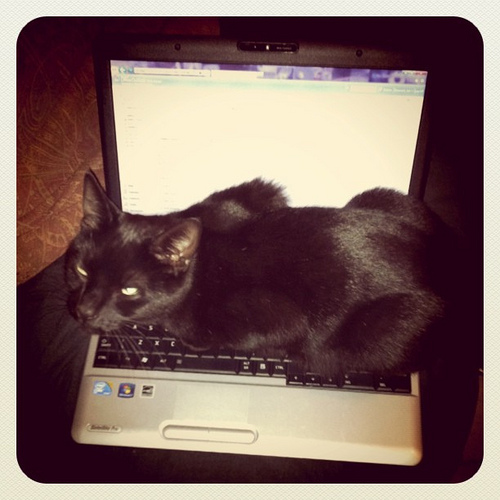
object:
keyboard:
[92, 323, 410, 393]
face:
[64, 228, 186, 332]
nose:
[75, 302, 98, 320]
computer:
[71, 33, 439, 467]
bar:
[173, 357, 240, 375]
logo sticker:
[117, 382, 135, 398]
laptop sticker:
[86, 423, 120, 433]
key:
[93, 351, 122, 368]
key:
[97, 335, 120, 351]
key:
[119, 353, 138, 368]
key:
[136, 351, 155, 370]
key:
[152, 354, 174, 370]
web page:
[111, 60, 428, 216]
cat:
[39, 166, 475, 379]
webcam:
[237, 42, 299, 52]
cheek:
[88, 294, 156, 331]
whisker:
[105, 318, 179, 369]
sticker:
[93, 380, 112, 397]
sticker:
[139, 381, 156, 398]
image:
[109, 58, 428, 85]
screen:
[94, 35, 443, 216]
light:
[329, 207, 410, 291]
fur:
[60, 162, 480, 382]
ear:
[150, 217, 202, 275]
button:
[162, 425, 254, 444]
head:
[33, 167, 202, 376]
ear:
[79, 168, 121, 232]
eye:
[76, 265, 87, 276]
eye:
[121, 286, 138, 295]